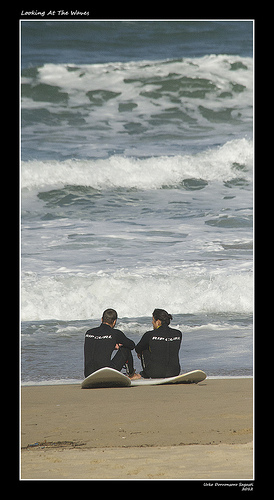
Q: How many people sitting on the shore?
A: Two.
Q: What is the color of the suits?
A: Black.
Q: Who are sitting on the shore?
A: A couple.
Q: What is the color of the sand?
A: Brown.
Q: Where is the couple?
A: At the beach.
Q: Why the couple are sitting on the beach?
A: They are resting.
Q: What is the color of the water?
A: Blue.